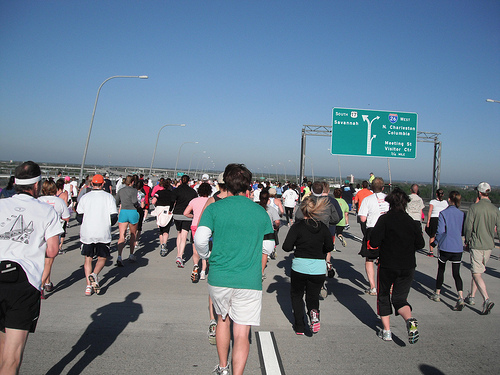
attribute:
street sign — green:
[373, 131, 397, 149]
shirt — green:
[194, 195, 273, 291]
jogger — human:
[74, 172, 117, 297]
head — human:
[89, 172, 106, 189]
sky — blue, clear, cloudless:
[2, 2, 496, 194]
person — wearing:
[72, 174, 120, 296]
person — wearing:
[0, 157, 68, 373]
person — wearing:
[115, 174, 147, 264]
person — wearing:
[357, 173, 387, 293]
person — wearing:
[188, 161, 278, 373]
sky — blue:
[4, 0, 499, 213]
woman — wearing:
[424, 187, 469, 314]